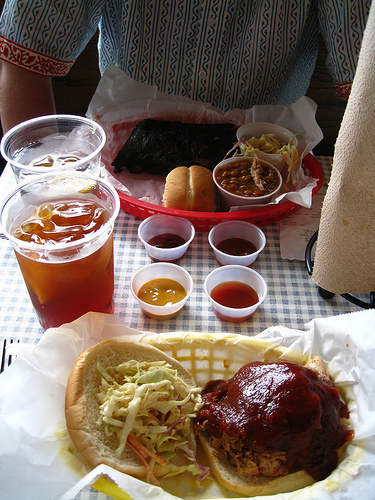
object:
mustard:
[144, 282, 180, 302]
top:
[181, 173, 209, 198]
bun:
[161, 165, 221, 212]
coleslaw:
[96, 358, 215, 491]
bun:
[64, 337, 198, 481]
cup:
[0, 171, 121, 332]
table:
[0, 156, 374, 500]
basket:
[92, 102, 324, 231]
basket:
[53, 329, 365, 500]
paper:
[56, 64, 324, 230]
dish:
[213, 156, 283, 212]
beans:
[229, 167, 247, 191]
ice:
[51, 204, 94, 227]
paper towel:
[310, 0, 375, 295]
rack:
[304, 229, 375, 309]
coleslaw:
[223, 132, 305, 185]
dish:
[236, 120, 298, 173]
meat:
[110, 118, 242, 174]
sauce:
[220, 366, 315, 430]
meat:
[209, 431, 289, 476]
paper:
[0, 311, 375, 500]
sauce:
[225, 287, 248, 303]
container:
[204, 265, 267, 323]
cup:
[208, 220, 267, 268]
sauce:
[227, 243, 252, 254]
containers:
[130, 262, 194, 321]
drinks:
[16, 146, 100, 194]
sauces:
[155, 236, 175, 244]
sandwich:
[64, 337, 355, 496]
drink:
[10, 197, 115, 330]